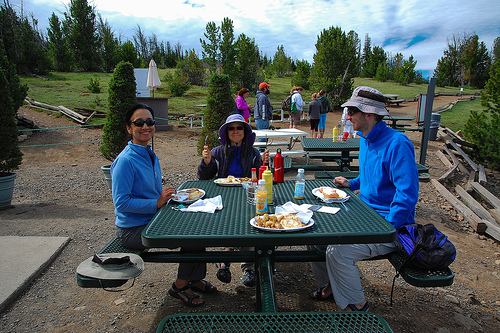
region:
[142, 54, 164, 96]
white folded umbrella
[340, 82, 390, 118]
tan floppy hat with a brown stripe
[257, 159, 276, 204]
red and yellow bottles of ketchup and mustard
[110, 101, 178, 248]
smiling woman in a blue sweater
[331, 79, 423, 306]
sitting man in a blue sweater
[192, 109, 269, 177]
woman in a hat holding a fork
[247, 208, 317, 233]
a plate of food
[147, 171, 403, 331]
a green metal picnic table with food on it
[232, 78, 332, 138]
a group of people in colorful clothes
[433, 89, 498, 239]
wooden edges of a path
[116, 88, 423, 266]
people enjoying a meal at a picnic table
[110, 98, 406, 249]
two women and a man eating a meal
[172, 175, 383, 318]
green mesh picnic table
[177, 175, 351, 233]
food on a green mesh picnic table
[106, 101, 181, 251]
woman in blue jacket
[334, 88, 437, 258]
man in blue jacket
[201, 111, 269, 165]
woman in purple hat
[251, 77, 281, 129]
man in red hat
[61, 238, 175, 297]
gray hat sitting on bench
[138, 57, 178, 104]
white umbrella in background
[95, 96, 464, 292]
two females and one male sitting at a table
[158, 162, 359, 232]
food and drinks on a table out doors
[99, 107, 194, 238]
a female smiling wearing a blue sweatshirt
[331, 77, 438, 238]
a male wearing a hat and a blue sweatshirt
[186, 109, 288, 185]
a female wearing a hat and jacket holding a fork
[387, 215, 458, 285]
a blue and black backpack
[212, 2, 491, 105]
green tall trees and green grass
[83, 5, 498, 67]
lots of white clouds in the sky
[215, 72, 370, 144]
six people standing out doors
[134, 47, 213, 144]
a white umbrella folded up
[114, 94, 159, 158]
woman has big smile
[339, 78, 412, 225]
man is watching woman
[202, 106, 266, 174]
other woman is wearing a hat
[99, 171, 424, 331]
picnic bench is green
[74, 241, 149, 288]
hat sitting on picnic bench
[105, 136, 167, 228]
light blue fleece jacket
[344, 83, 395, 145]
man wearing brown and tan jacket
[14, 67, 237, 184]
several potted trees behind bench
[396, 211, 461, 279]
backpack on bench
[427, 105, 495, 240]
wood fence on the trail edge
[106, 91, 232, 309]
lady sitting at picnic table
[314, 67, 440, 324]
man sitting at picnic table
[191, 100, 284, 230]
lady sitting at picnic table holding knife and fork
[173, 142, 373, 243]
food on the table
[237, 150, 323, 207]
condiments on table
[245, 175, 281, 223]
orange juice on table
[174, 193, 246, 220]
napkin on picnic table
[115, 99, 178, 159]
lady wearing sunglasses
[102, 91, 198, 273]
lady wearing blue sweater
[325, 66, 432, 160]
man wearing grey and black hat